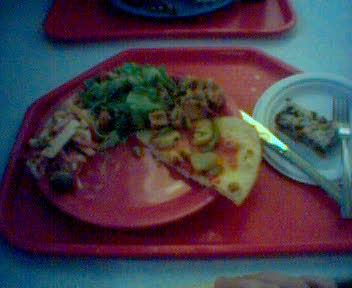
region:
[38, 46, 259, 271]
a piece of food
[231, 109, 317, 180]
a knief near food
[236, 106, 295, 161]
sharp edge of knief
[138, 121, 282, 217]
a piece of burger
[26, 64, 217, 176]
a group of food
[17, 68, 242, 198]
a group of food items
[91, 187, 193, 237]
round part of plate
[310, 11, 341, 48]
the table is white in color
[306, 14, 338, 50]
the table is clean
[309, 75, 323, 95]
this is a saucer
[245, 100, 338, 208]
this is a knife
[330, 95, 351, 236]
this is a fork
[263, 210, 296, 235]
this is the tray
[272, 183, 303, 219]
the tray is red in color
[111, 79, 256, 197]
this is some pizza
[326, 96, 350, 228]
fork on the plate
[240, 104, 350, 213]
knife on the plate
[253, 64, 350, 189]
white plate on tray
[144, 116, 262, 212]
slice of pizza on plate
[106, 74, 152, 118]
green lettuce on plate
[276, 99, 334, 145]
chocolate chip cookie on plate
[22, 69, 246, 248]
red plate on the tray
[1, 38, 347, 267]
red tray on the table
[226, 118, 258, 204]
crust on the pizza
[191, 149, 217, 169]
topping on the pizza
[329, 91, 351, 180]
A fork resting on a plate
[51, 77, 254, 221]
A partially eaten pizza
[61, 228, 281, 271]
The edge of a plastic red serving tray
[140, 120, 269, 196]
One piece of pizza on a plate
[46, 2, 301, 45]
The edge of a lunch tray with a blue plate on it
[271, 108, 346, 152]
A rectangular piece of dessert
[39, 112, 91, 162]
Various pizza toppings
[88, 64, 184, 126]
A pizza topped with spinach leaves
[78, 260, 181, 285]
A section of blue colored table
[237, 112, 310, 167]
A silver reflective knife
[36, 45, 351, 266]
a part of food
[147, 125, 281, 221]
a piece of food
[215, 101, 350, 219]
a knief in table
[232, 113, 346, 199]
a knief on the plate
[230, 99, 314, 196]
a knief beside food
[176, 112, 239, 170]
decoration on the food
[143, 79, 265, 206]
decoration on the pizza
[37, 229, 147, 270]
a red plate in the table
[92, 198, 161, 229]
a round part of plate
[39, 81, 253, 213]
a group of food items